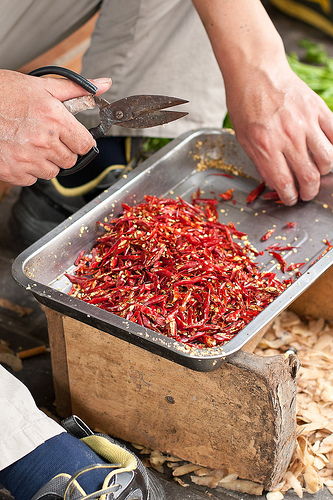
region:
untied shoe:
[33, 459, 164, 495]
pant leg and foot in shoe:
[0, 362, 164, 494]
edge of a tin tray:
[9, 217, 57, 312]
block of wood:
[149, 368, 297, 453]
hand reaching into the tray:
[211, 54, 322, 205]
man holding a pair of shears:
[4, 51, 186, 184]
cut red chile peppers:
[129, 228, 221, 309]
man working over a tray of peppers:
[28, 28, 317, 275]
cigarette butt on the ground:
[14, 336, 45, 357]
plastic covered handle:
[28, 58, 96, 94]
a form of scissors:
[45, 65, 201, 183]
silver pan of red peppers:
[0, 120, 294, 363]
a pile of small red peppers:
[102, 199, 274, 331]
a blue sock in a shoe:
[13, 436, 111, 498]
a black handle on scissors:
[24, 61, 100, 94]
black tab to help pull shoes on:
[63, 409, 97, 441]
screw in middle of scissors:
[113, 108, 128, 123]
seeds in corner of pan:
[196, 146, 249, 182]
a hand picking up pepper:
[212, 72, 331, 214]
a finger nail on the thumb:
[90, 70, 112, 88]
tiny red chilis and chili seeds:
[82, 193, 271, 338]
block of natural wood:
[37, 310, 330, 493]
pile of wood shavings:
[288, 323, 331, 471]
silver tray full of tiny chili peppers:
[37, 150, 305, 365]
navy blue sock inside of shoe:
[5, 428, 125, 499]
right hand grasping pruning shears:
[0, 54, 188, 184]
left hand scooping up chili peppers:
[217, 80, 330, 215]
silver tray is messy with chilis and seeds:
[39, 114, 323, 376]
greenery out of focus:
[282, 33, 331, 101]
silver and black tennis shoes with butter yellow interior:
[16, 420, 160, 498]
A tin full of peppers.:
[75, 168, 331, 359]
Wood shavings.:
[138, 271, 327, 498]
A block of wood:
[43, 306, 292, 491]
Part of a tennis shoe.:
[18, 412, 174, 498]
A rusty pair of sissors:
[29, 68, 192, 179]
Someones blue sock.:
[0, 424, 129, 497]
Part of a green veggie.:
[281, 35, 332, 126]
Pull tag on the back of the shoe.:
[60, 415, 95, 443]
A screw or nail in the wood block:
[160, 394, 178, 407]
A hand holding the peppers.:
[186, 0, 331, 213]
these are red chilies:
[61, 197, 284, 341]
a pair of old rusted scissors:
[27, 43, 184, 189]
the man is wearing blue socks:
[6, 417, 106, 495]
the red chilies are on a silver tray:
[15, 122, 309, 348]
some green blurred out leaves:
[298, 21, 329, 99]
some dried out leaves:
[280, 318, 328, 482]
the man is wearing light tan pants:
[112, 6, 214, 123]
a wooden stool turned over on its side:
[79, 342, 299, 452]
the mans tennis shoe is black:
[11, 162, 118, 231]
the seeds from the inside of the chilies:
[190, 139, 238, 178]